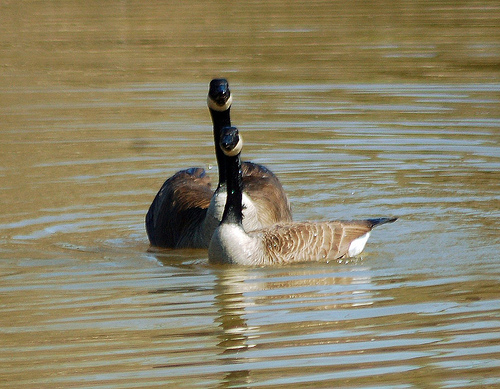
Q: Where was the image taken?
A: It was taken at the shore.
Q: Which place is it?
A: It is a shore.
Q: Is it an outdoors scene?
A: Yes, it is outdoors.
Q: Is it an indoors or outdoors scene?
A: It is outdoors.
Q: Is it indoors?
A: No, it is outdoors.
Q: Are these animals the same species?
A: Yes, all the animals are birds.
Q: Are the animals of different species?
A: No, all the animals are birds.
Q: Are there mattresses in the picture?
A: No, there are no mattresses.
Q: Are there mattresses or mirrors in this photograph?
A: No, there are no mattresses or mirrors.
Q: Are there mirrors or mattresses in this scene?
A: No, there are no mattresses or mirrors.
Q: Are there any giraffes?
A: No, there are no giraffes.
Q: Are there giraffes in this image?
A: No, there are no giraffes.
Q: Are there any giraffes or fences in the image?
A: No, there are no giraffes or fences.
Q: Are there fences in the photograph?
A: No, there are no fences.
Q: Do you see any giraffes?
A: No, there are no giraffes.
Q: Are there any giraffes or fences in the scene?
A: No, there are no giraffes or fences.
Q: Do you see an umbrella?
A: No, there are no umbrellas.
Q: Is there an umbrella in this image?
A: No, there are no umbrellas.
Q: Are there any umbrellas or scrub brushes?
A: No, there are no umbrellas or scrub brushes.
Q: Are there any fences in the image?
A: No, there are no fences.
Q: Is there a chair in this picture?
A: No, there are no chairs.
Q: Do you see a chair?
A: No, there are no chairs.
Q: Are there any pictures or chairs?
A: No, there are no chairs or pictures.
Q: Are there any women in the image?
A: Yes, there is a woman.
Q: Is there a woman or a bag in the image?
A: Yes, there is a woman.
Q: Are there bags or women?
A: Yes, there is a woman.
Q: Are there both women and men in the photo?
A: No, there is a woman but no men.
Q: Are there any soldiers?
A: No, there are no soldiers.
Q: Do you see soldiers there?
A: No, there are no soldiers.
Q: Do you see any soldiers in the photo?
A: No, there are no soldiers.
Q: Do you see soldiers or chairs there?
A: No, there are no soldiers or chairs.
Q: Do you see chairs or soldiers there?
A: No, there are no soldiers or chairs.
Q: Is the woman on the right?
A: Yes, the woman is on the right of the image.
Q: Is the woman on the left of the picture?
A: No, the woman is on the right of the image.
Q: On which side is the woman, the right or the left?
A: The woman is on the right of the image.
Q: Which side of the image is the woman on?
A: The woman is on the right of the image.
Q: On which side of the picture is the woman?
A: The woman is on the right of the image.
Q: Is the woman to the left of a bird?
A: No, the woman is to the right of a bird.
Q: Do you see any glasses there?
A: No, there are no glasses.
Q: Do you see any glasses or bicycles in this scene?
A: No, there are no glasses or bicycles.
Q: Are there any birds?
A: Yes, there is a bird.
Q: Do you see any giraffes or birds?
A: Yes, there is a bird.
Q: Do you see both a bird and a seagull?
A: No, there is a bird but no seagulls.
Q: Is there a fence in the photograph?
A: No, there are no fences.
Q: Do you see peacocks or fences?
A: No, there are no fences or peacocks.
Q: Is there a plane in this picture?
A: No, there are no airplanes.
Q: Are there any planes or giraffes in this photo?
A: No, there are no planes or giraffes.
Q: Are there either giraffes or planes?
A: No, there are no planes or giraffes.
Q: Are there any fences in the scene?
A: No, there are no fences.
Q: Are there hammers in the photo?
A: No, there are no hammers.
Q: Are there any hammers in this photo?
A: No, there are no hammers.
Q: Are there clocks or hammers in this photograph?
A: No, there are no hammers or clocks.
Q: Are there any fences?
A: No, there are no fences.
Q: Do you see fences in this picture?
A: No, there are no fences.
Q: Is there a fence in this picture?
A: No, there are no fences.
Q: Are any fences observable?
A: No, there are no fences.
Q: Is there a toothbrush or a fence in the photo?
A: No, there are no fences or toothbrushes.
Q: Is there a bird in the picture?
A: Yes, there is a bird.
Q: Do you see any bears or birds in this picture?
A: Yes, there is a bird.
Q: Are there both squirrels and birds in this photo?
A: No, there is a bird but no squirrels.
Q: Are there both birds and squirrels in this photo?
A: No, there is a bird but no squirrels.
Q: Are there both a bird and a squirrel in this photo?
A: No, there is a bird but no squirrels.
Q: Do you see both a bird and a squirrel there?
A: No, there is a bird but no squirrels.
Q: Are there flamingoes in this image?
A: No, there are no flamingoes.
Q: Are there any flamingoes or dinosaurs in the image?
A: No, there are no flamingoes or dinosaurs.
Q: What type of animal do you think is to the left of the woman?
A: The animal is a bird.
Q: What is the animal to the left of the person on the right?
A: The animal is a bird.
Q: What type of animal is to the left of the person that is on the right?
A: The animal is a bird.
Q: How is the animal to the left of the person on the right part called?
A: The animal is a bird.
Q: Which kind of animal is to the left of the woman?
A: The animal is a bird.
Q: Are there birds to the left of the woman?
A: Yes, there is a bird to the left of the woman.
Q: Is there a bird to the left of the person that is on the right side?
A: Yes, there is a bird to the left of the woman.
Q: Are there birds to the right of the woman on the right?
A: No, the bird is to the left of the woman.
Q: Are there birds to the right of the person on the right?
A: No, the bird is to the left of the woman.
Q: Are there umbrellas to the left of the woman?
A: No, there is a bird to the left of the woman.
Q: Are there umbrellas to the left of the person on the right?
A: No, there is a bird to the left of the woman.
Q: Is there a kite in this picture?
A: No, there are no kites.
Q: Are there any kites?
A: No, there are no kites.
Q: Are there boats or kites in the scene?
A: No, there are no kites or boats.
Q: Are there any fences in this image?
A: No, there are no fences.